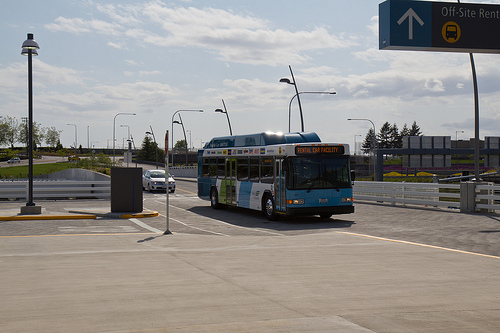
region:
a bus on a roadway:
[187, 107, 385, 247]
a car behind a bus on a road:
[140, 131, 237, 216]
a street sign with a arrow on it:
[370, 1, 487, 58]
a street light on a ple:
[9, 24, 40, 221]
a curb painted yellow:
[5, 203, 161, 228]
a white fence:
[372, 177, 463, 208]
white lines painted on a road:
[146, 179, 261, 254]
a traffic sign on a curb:
[150, 126, 174, 262]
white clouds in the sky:
[147, 9, 348, 62]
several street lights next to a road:
[60, 93, 255, 153]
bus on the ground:
[163, 95, 382, 241]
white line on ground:
[359, 205, 434, 272]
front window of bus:
[276, 148, 359, 212]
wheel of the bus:
[230, 184, 288, 242]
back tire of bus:
[191, 173, 234, 218]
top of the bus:
[199, 115, 322, 162]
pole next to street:
[8, 37, 68, 167]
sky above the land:
[101, 41, 187, 94]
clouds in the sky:
[98, 31, 230, 102]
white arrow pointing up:
[392, 7, 438, 41]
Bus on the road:
[190, 127, 355, 229]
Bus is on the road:
[191, 130, 360, 222]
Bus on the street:
[195, 131, 360, 224]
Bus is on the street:
[198, 127, 358, 226]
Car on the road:
[141, 168, 178, 196]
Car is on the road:
[143, 163, 179, 195]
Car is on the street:
[138, 167, 178, 194]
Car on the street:
[141, 165, 179, 195]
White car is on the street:
[140, 161, 177, 193]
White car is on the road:
[140, 165, 180, 193]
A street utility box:
[101, 161, 153, 223]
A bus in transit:
[189, 124, 376, 235]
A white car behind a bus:
[138, 137, 370, 233]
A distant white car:
[141, 166, 180, 198]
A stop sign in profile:
[133, 126, 183, 262]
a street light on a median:
[11, 20, 54, 245]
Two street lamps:
[200, 51, 337, 128]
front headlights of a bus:
[287, 193, 353, 210]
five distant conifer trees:
[359, 117, 440, 160]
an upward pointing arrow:
[394, 2, 430, 43]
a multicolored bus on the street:
[195, 128, 357, 215]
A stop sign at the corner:
[160, 127, 175, 235]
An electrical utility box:
[106, 161, 146, 217]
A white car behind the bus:
[143, 167, 176, 196]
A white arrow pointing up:
[396, 5, 424, 42]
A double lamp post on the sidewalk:
[20, 29, 42, 216]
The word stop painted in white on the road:
[56, 222, 138, 236]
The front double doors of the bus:
[270, 155, 287, 214]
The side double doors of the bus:
[220, 156, 240, 203]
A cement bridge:
[38, 164, 204, 198]